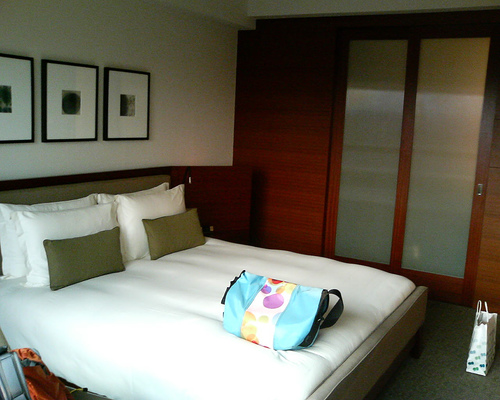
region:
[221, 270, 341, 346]
a colorful purse sitting on the bed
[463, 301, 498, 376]
a shopping bag sitting on the floor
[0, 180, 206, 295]
the pillows sitting on the bed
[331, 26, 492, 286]
the door to the closet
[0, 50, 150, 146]
the photos handing on the wall above the bed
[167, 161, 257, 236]
a cabinet next to the bed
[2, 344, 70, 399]
a bag sitting next to the bed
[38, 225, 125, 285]
a little brown pillow sitting on the bed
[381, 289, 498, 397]
the grey carpet sitting on the floor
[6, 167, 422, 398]
the big bed in the bedroom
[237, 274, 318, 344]
bag on the bed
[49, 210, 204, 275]
green rectangle throw pillows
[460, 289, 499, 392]
bag on the floor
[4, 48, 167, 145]
pictures on the wall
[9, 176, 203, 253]
the headboard on the bed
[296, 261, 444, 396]
the footboard on the bed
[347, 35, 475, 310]
the opaque double doors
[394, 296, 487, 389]
carpet on the ground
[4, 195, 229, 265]
white pillows on the bed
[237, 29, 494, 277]
the wood wall by the doors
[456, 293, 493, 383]
white bag on the floor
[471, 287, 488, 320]
handles on the white bag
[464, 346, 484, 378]
blue spots on the bag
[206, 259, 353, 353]
blue purse on the bed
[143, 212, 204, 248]
green pillow on bed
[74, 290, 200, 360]
white sheet on the bed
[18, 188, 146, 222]
large white pillows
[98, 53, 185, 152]
large picture on the wall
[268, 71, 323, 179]
wood paneling on the walls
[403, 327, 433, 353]
black bed foot on the ground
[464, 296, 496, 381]
white paper shopping bag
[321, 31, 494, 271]
glass panel closet door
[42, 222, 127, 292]
army green rectangular throw pillow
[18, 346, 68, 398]
small orange bag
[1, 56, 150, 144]
set of three black and white photos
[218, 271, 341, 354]
blue and white tote bag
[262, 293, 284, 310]
small purple circle decoration on tote bag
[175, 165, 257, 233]
red wood side of headboard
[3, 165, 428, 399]
large bed with white sheets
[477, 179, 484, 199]
small silver door pull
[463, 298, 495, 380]
Bag on the floor.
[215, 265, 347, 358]
Bag on the bed.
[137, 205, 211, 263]
Green pillow on the bed.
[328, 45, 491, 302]
Door in the wall.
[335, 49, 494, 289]
Glass panels in the door.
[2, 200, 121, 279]
White pillows on the bed.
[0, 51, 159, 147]
pictures on the wall.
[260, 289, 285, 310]
Purple circle on the bag.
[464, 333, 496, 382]
Blue rectangles on the bag.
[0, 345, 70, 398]
Orange backpack beside the bed.